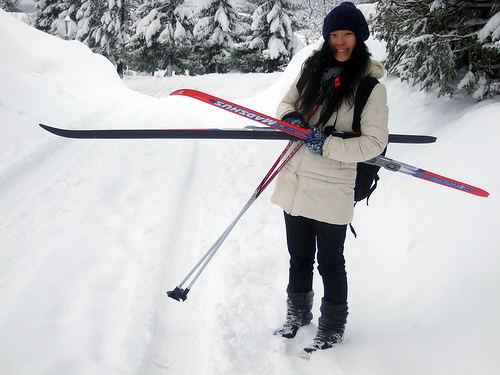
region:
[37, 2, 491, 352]
a woman is holding skis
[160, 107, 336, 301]
a woman holding ski poles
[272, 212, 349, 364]
a woman's pants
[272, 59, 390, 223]
a woman's white jacket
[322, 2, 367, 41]
a woman's blue hat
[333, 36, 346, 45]
woman has a nose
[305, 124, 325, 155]
a woman's gloved hand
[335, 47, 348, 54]
a woman's open mouth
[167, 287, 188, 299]
tip of two ski poles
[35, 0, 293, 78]
trees covered in snow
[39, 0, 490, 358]
A woman holding skis and ski poles.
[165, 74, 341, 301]
A pair of ski poles.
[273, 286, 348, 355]
Black boots on the woman's feet.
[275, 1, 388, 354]
A woman standing and smiling.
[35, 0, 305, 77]
A group of snow covered trees.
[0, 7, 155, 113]
A large mound of snow.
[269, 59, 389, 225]
A medium length coat.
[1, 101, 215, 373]
Tracks in the snow.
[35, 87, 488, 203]
A pair of skis.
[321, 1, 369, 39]
A black knitted cap.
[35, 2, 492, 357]
a woman holds a pair of skis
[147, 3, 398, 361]
a woman holds a pair of ski poles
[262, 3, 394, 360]
a womans feet are covered in snow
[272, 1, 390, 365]
woman wears a black knitted hat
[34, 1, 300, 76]
trees are covered in snow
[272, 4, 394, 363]
woman is smiling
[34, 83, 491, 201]
skis are red silver and black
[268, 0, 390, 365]
woman wears an off-white ski jacket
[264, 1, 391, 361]
woman has a backpack on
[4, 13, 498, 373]
ground is very snowy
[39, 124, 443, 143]
a dark colored ski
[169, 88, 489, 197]
a red ski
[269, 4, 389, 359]
a woman in winter clothing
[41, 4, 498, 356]
a woman in winter clothing is holding ski gear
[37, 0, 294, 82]
trees are covered in snow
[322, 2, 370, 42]
a blue hat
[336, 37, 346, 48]
nose of a woman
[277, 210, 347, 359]
a woman's blue jean pants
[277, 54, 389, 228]
a woman's white jacket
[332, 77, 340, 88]
a red band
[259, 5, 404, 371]
a lady standing the snow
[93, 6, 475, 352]
a lady holding skis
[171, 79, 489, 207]
a red ski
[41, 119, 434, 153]
a black ski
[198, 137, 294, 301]
the red ski poles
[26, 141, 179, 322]
tracks in the snow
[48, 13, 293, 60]
trees with snow on them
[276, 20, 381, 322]
a lady wearing a white jacket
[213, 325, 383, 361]
snow on the ground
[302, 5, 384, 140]
a lady wearing a cap